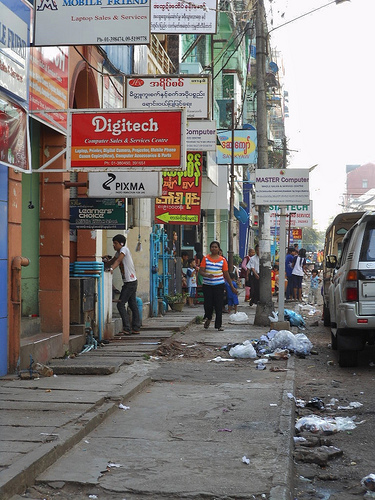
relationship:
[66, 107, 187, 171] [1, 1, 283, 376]
board attached to building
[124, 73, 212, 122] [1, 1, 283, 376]
board attached to building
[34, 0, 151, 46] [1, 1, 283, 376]
board attached to building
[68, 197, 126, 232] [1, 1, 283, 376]
board attached to building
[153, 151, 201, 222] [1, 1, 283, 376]
board attached to building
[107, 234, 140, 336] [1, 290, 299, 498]
man on sidewalk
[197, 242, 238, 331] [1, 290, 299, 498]
person on sidewalk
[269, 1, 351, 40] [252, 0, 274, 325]
light attached to pole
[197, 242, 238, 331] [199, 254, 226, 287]
woman has shirt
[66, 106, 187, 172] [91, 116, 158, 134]
board says digitech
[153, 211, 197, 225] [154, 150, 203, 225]
arrow on board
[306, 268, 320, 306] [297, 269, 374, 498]
child in road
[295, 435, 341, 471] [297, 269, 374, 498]
rock in road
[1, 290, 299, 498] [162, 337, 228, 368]
sidewalk has dip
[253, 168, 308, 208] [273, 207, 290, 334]
sign on pole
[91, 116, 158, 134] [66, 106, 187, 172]
digitech on board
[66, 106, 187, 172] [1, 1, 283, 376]
board on building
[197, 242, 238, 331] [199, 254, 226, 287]
person has shirt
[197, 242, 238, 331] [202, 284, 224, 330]
person has pants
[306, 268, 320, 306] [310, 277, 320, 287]
child has shirt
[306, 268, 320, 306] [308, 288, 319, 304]
child has pants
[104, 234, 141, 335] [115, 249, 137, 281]
man has shirt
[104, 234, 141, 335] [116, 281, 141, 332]
man has pants